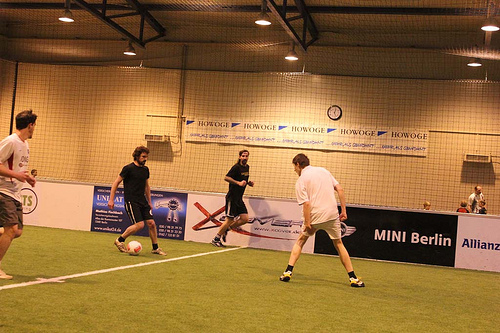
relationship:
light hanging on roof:
[123, 43, 137, 57] [0, 1, 499, 81]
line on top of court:
[0, 245, 248, 291] [0, 225, 499, 332]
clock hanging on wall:
[326, 105, 343, 121] [1, 59, 499, 215]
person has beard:
[106, 146, 166, 256] [136, 157, 147, 165]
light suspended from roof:
[123, 43, 137, 57] [0, 1, 499, 81]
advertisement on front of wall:
[90, 184, 190, 241] [23, 179, 500, 274]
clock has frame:
[326, 105, 343, 121] [326, 105, 343, 120]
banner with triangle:
[180, 115, 431, 156] [186, 119, 196, 125]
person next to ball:
[106, 146, 166, 256] [127, 240, 142, 256]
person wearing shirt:
[280, 153, 365, 286] [295, 165, 340, 226]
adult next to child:
[468, 186, 486, 213] [456, 200, 470, 213]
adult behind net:
[468, 186, 486, 213] [1, 0, 498, 214]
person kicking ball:
[106, 146, 166, 256] [127, 240, 142, 256]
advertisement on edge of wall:
[90, 184, 190, 241] [23, 179, 500, 274]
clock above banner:
[326, 105, 343, 121] [180, 115, 431, 156]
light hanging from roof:
[123, 43, 137, 57] [0, 1, 499, 81]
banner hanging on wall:
[180, 115, 431, 156] [1, 59, 499, 215]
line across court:
[0, 245, 248, 291] [0, 225, 499, 332]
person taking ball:
[106, 146, 166, 256] [127, 240, 142, 256]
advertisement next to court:
[90, 184, 190, 241] [0, 225, 499, 332]